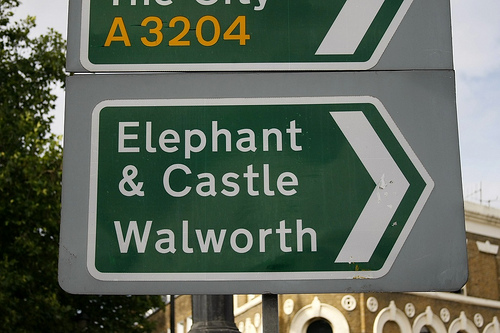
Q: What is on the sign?
A: Elephant & Castle Walworth.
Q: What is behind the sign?
A: A building.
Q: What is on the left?
A: A tree.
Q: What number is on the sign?
A: 3204.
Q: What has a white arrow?
A: Sign.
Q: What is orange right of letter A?
A: Numbers.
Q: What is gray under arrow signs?
A: Sign background.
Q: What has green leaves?
A: Tree.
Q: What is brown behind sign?
A: Building.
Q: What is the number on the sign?
A: 3204.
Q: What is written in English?
A: Words on sign.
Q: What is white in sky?
A: Clouds.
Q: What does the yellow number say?
A: A3204.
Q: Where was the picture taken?
A: Zoo.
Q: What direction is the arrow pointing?
A: Right.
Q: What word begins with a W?
A: Walworth.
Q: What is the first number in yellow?
A: 3.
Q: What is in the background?
A: Building.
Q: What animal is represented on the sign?
A: Elephant.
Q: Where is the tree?
A: On the left.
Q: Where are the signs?
A: Attached to a pole.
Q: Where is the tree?
A: Next to the building.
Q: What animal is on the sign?
A: Elephant.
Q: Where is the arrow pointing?
A: To the right.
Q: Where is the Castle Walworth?
A: To the right.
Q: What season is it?
A: Summer.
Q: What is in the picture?
A: A street sign.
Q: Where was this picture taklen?
A: The street.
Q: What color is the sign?
A: Green and white.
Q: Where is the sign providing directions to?
A: Elephant and Castle.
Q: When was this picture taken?
A: Daytime.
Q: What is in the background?
A: A building.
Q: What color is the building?
A: Brown and white.